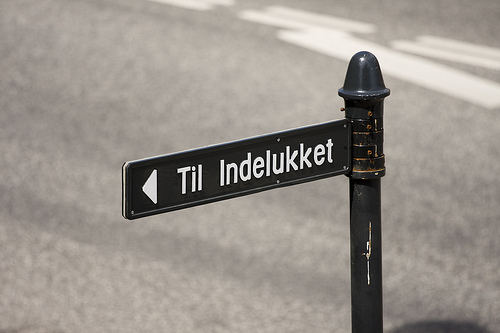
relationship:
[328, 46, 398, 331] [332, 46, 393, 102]
pole has tip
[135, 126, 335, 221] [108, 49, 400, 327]
til indelukket written on sign post